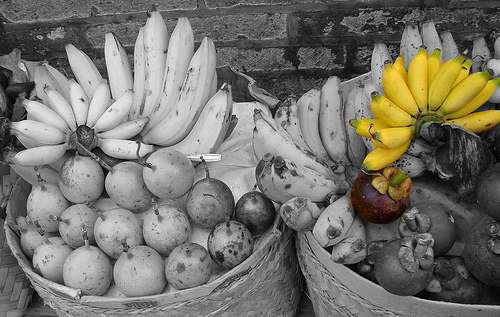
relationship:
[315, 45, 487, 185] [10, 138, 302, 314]
banana in basket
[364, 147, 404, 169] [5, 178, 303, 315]
bananas in basket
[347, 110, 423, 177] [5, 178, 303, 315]
banana in basket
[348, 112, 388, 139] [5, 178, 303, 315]
banana in basket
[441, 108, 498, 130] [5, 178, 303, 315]
banana in basket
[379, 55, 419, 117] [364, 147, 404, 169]
banana in bananas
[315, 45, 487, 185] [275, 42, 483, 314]
banana in basket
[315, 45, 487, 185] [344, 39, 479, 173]
banana in bunch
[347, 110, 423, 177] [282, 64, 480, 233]
banana in bunch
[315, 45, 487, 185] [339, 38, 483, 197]
banana in bunch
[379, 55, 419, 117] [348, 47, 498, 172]
banana in bunch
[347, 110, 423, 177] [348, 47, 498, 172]
banana in bunch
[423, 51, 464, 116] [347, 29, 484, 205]
banana in bunch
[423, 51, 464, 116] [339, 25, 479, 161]
banana in bunch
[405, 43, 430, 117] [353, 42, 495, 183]
banana in bunch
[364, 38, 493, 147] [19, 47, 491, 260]
bananas in bunches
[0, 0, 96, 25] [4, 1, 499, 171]
brick in a wall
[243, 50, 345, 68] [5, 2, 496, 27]
brick in a wall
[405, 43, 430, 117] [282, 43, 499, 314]
banana in basket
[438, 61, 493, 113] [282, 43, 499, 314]
banana in basket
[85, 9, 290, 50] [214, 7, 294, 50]
brick in wall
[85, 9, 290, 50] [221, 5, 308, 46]
brick in wall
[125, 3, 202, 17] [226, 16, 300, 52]
brick in wall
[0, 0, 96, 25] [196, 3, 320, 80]
brick in wall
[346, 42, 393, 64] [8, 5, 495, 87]
brick in wall